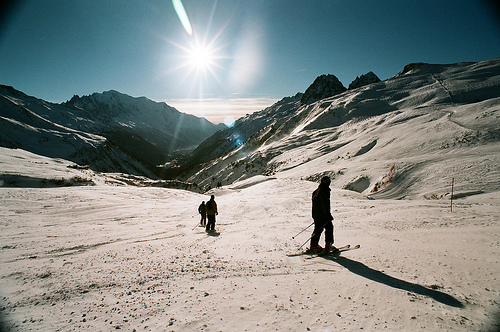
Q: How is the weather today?
A: It is clear.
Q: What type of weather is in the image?
A: It is clear.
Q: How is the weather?
A: It is clear.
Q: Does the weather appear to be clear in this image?
A: Yes, it is clear.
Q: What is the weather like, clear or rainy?
A: It is clear.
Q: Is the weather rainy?
A: No, it is clear.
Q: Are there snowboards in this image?
A: No, there are no snowboards.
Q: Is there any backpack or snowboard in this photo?
A: No, there are no snowboards or backpacks.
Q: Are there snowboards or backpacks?
A: No, there are no snowboards or backpacks.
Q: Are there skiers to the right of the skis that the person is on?
A: Yes, there is a skier to the right of the skis.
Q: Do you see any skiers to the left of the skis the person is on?
A: No, the skier is to the right of the skis.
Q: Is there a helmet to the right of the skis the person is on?
A: No, there is a skier to the right of the skis.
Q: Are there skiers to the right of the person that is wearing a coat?
A: Yes, there is a skier to the right of the person.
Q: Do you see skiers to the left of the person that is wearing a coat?
A: No, the skier is to the right of the person.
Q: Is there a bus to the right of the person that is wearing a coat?
A: No, there is a skier to the right of the person.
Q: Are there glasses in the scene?
A: No, there are no glasses.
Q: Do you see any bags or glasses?
A: No, there are no glasses or bags.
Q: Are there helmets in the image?
A: No, there are no helmets.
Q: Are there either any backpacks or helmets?
A: No, there are no helmets or backpacks.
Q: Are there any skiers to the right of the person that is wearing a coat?
A: Yes, there is a skier to the right of the person.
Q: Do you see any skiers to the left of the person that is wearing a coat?
A: No, the skier is to the right of the person.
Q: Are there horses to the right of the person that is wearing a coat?
A: No, there is a skier to the right of the person.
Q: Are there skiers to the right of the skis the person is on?
A: Yes, there is a skier to the right of the skis.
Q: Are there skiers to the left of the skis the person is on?
A: No, the skier is to the right of the skis.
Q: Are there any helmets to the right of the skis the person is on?
A: No, there is a skier to the right of the skis.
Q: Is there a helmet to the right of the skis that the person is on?
A: No, there is a skier to the right of the skis.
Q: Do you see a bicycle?
A: No, there are no bicycles.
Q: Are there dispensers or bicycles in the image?
A: No, there are no bicycles or dispensers.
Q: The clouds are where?
A: The clouds are in the sky.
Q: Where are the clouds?
A: The clouds are in the sky.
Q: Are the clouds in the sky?
A: Yes, the clouds are in the sky.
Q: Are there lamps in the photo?
A: No, there are no lamps.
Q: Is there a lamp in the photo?
A: No, there are no lamps.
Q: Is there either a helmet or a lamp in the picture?
A: No, there are no lamps or helmets.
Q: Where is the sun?
A: The sun is in the sky.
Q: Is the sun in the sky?
A: Yes, the sun is in the sky.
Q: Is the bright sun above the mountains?
A: Yes, the sun is above the mountains.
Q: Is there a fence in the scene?
A: No, there are no fences.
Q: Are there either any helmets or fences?
A: No, there are no fences or helmets.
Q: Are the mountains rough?
A: Yes, the mountains are rough.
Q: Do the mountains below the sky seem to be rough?
A: Yes, the mountains are rough.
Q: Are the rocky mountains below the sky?
A: Yes, the mountains are below the sky.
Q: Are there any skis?
A: Yes, there are skis.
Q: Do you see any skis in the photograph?
A: Yes, there are skis.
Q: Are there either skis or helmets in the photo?
A: Yes, there are skis.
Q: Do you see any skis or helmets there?
A: Yes, there are skis.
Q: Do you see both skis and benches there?
A: No, there are skis but no benches.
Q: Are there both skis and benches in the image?
A: No, there are skis but no benches.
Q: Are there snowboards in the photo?
A: No, there are no snowboards.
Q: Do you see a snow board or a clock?
A: No, there are no snowboards or clocks.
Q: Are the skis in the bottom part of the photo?
A: Yes, the skis are in the bottom of the image.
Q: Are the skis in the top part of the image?
A: No, the skis are in the bottom of the image.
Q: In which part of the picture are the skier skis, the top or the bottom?
A: The skis are in the bottom of the image.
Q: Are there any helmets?
A: No, there are no helmets.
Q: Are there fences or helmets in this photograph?
A: No, there are no helmets or fences.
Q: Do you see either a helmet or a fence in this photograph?
A: No, there are no helmets or fences.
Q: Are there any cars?
A: No, there are no cars.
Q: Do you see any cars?
A: No, there are no cars.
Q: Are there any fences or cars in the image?
A: No, there are no cars or fences.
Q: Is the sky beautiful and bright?
A: Yes, the sky is beautiful and bright.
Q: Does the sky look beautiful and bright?
A: Yes, the sky is beautiful and bright.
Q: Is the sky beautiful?
A: Yes, the sky is beautiful.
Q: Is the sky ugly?
A: No, the sky is beautiful.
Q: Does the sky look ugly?
A: No, the sky is beautiful.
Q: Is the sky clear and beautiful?
A: Yes, the sky is clear and beautiful.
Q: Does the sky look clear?
A: Yes, the sky is clear.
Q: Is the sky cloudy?
A: No, the sky is clear.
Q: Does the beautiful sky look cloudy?
A: No, the sky is clear.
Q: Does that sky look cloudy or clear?
A: The sky is clear.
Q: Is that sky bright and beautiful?
A: Yes, the sky is bright and beautiful.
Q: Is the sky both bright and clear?
A: Yes, the sky is bright and clear.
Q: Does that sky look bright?
A: Yes, the sky is bright.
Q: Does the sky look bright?
A: Yes, the sky is bright.